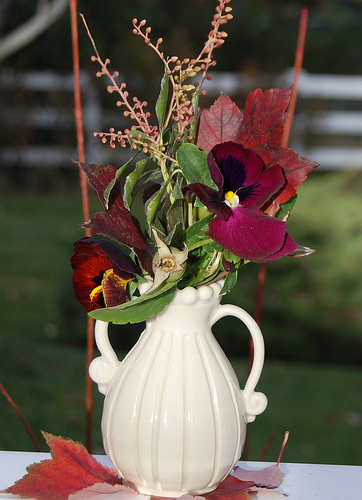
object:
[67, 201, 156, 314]
flower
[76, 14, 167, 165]
flower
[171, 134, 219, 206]
leaf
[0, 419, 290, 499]
leaves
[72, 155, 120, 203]
leaves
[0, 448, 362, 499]
table top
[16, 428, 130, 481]
petal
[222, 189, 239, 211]
center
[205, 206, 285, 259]
petal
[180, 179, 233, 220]
petal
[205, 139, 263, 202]
petal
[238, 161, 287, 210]
petal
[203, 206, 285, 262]
flower petal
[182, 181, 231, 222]
flower petal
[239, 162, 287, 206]
flower petal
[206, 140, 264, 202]
flower petal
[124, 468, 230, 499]
base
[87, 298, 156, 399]
handle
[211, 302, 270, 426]
handle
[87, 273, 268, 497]
vase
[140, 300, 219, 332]
short neck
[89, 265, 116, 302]
yellow edges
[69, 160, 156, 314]
flowers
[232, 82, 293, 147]
leaf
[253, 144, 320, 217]
leaf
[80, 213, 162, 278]
leaf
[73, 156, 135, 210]
leaf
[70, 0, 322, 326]
flower arrangement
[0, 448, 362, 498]
table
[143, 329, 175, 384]
grooves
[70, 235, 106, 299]
petals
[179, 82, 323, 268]
flower